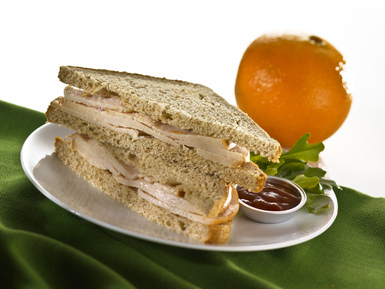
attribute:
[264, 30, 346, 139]
orange — sitting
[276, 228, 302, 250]
plate — white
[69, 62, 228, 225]
sandwhich — brown, turkey, sliced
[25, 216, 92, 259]
table — green